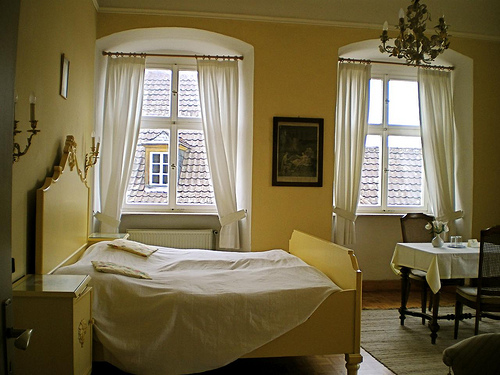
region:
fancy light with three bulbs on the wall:
[71, 124, 108, 186]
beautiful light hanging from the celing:
[369, 5, 464, 80]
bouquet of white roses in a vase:
[416, 221, 453, 258]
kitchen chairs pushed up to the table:
[391, 208, 498, 320]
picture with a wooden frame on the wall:
[261, 103, 338, 201]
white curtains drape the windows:
[74, 23, 264, 253]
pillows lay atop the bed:
[84, 231, 164, 309]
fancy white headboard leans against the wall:
[30, 128, 97, 286]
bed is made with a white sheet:
[60, 213, 365, 369]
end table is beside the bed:
[6, 259, 91, 374]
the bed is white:
[154, 277, 221, 334]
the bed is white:
[214, 333, 234, 361]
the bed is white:
[225, 301, 259, 366]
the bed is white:
[168, 250, 200, 279]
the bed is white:
[231, 287, 282, 370]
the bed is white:
[153, 199, 288, 366]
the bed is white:
[165, 289, 276, 368]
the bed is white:
[140, 254, 222, 370]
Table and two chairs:
[393, 196, 498, 343]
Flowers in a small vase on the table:
[423, 215, 453, 250]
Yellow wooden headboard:
[29, 127, 97, 269]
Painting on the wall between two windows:
[267, 109, 327, 193]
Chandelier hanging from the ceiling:
[375, 0, 453, 70]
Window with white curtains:
[91, 44, 251, 241]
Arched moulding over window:
[94, 22, 258, 53]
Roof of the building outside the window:
[133, 68, 209, 207]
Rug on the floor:
[357, 300, 498, 372]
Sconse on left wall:
[5, 85, 46, 170]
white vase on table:
[421, 215, 448, 252]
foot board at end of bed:
[281, 216, 374, 363]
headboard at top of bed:
[19, 142, 107, 252]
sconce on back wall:
[77, 126, 108, 180]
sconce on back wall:
[6, 98, 51, 158]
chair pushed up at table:
[469, 225, 495, 325]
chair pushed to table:
[391, 213, 428, 241]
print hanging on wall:
[259, 112, 326, 194]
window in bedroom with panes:
[358, 80, 419, 202]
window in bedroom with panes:
[117, 67, 214, 204]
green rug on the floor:
[372, 317, 447, 373]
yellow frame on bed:
[280, 215, 389, 295]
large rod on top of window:
[93, 36, 268, 66]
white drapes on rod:
[95, 51, 260, 220]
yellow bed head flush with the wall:
[7, 132, 132, 235]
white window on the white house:
[142, 144, 178, 188]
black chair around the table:
[374, 201, 452, 298]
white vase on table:
[410, 210, 458, 249]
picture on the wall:
[258, 100, 333, 209]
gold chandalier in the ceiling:
[359, 8, 476, 86]